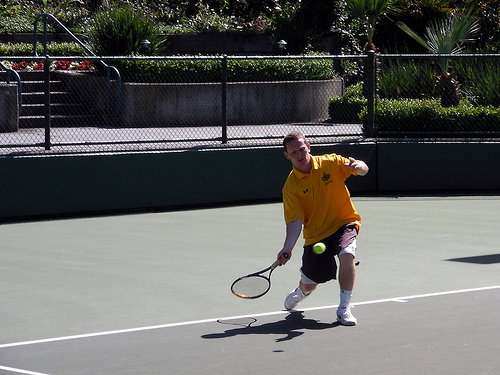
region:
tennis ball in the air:
[307, 239, 327, 259]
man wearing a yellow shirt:
[270, 164, 360, 238]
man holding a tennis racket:
[223, 234, 295, 291]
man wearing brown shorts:
[291, 218, 355, 275]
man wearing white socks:
[334, 284, 356, 306]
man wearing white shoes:
[326, 303, 362, 330]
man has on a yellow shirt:
[281, 154, 361, 246]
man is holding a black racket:
[230, 255, 288, 299]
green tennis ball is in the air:
[310, 242, 325, 254]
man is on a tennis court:
[277, 132, 369, 327]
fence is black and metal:
[0, 51, 497, 152]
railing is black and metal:
[34, 12, 122, 129]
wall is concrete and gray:
[116, 80, 345, 126]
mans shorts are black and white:
[300, 226, 361, 286]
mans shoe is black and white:
[284, 289, 310, 316]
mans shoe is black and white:
[335, 306, 357, 327]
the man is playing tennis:
[202, 112, 357, 314]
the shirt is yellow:
[277, 175, 367, 255]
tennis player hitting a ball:
[220, 127, 380, 338]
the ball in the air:
[304, 234, 338, 261]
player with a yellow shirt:
[262, 119, 381, 331]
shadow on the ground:
[193, 307, 323, 349]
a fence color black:
[3, 51, 498, 136]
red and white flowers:
[6, 44, 96, 79]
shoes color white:
[278, 282, 359, 328]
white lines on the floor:
[0, 279, 499, 373]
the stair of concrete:
[16, 56, 82, 133]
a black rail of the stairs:
[26, 6, 118, 80]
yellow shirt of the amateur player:
[277, 151, 362, 245]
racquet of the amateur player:
[235, 255, 287, 300]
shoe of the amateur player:
[333, 300, 356, 325]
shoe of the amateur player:
[281, 285, 302, 311]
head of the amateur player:
[277, 130, 312, 170]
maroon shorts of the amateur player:
[296, 225, 358, 286]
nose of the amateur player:
[295, 150, 305, 156]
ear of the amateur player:
[281, 147, 289, 158]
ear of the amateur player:
[305, 136, 312, 151]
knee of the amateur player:
[338, 245, 357, 267]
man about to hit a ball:
[228, 131, 369, 328]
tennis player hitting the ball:
[230, 132, 369, 329]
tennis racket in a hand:
[229, 253, 292, 300]